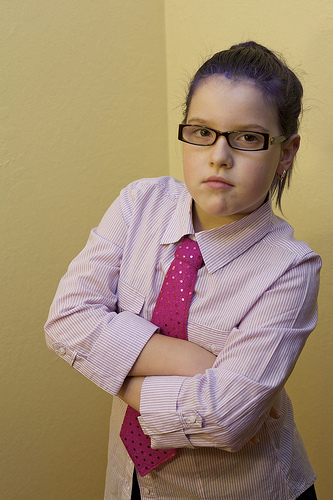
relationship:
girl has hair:
[42, 40, 324, 499] [181, 42, 308, 215]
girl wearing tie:
[42, 40, 324, 499] [119, 236, 204, 471]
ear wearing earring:
[276, 132, 300, 175] [275, 167, 286, 179]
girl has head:
[42, 40, 323, 493] [155, 50, 306, 256]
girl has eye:
[42, 40, 324, 499] [241, 132, 263, 142]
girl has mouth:
[42, 40, 324, 499] [200, 174, 235, 189]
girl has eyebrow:
[42, 40, 324, 499] [237, 123, 270, 132]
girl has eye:
[42, 40, 323, 493] [238, 130, 260, 145]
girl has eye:
[42, 40, 323, 493] [192, 125, 209, 135]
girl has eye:
[42, 40, 323, 493] [235, 133, 255, 141]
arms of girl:
[52, 308, 235, 416] [80, 44, 299, 477]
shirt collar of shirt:
[159, 179, 266, 275] [39, 171, 319, 497]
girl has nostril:
[42, 40, 324, 499] [219, 161, 229, 168]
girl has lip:
[42, 40, 324, 499] [204, 175, 231, 184]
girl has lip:
[42, 40, 324, 499] [204, 181, 232, 188]